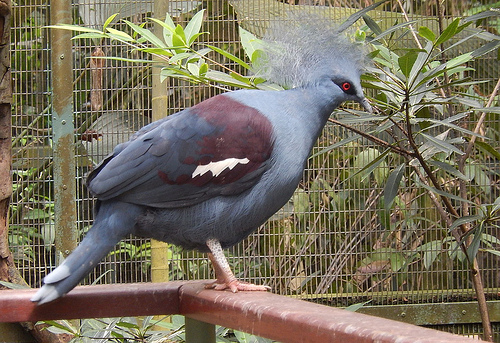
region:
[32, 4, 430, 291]
ugly bird sitting on a red porch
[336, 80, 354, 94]
red eye on the bird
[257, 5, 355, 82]
fluffy feather on the bird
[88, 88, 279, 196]
multi colored wing on the bird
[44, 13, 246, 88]
green leaves growing out of plant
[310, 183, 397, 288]
wire fence near the bird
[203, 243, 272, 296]
foot of the ugly bird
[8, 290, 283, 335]
red metal railing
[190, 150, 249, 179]
white spot on the birds wing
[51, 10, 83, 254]
metal pole on the wire fence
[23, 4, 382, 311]
close-up of a grey exotic bird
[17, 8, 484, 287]
fence of a gate enclosure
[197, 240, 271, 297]
legs of a bird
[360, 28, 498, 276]
a tree in a bird enclosure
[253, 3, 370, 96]
light grey plume of feathers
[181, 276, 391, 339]
red metal railing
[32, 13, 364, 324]
bird perched on a railing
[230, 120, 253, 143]
portion of dark red feathers on a bird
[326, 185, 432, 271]
mixed foliage in an enclosure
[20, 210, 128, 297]
grey and white tail feathers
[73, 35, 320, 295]
Bird in the cage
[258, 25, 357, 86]
Bird with weathers raised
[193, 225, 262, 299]
bird with feet on pole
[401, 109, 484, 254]
leaves on a tree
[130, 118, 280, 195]
Bird with blue and red feathers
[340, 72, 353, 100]
bird with red eyes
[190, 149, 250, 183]
bird with white feathers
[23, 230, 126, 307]
bird with long feather tail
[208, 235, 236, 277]
bird with skinny legs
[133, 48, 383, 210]
bird in a cage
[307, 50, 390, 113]
head of the bird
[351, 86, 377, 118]
beak of the bird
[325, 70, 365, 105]
eye of the bird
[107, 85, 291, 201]
feathers of the bird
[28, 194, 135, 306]
tail feathers of the bird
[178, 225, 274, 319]
legs of the bird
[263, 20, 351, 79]
hair on the bird's head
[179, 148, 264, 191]
white part of the feathers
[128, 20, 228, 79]
leaves next to bird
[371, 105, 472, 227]
branches on the tree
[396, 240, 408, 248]
part of a fence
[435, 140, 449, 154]
part of a plant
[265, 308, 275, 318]
part of a rail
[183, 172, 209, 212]
part of a feather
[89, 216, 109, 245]
back of a feather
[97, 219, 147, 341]
side of a bird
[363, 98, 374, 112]
beak of a bird